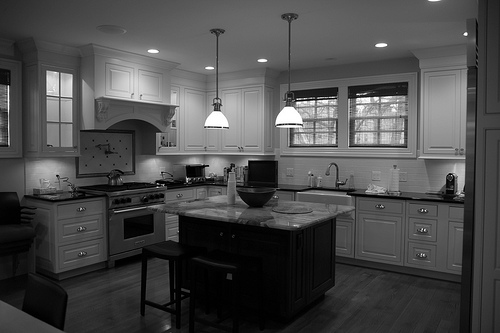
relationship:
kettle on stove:
[104, 168, 124, 188] [80, 181, 165, 196]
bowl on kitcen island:
[236, 186, 276, 208] [160, 202, 353, 319]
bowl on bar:
[236, 186, 276, 208] [146, 194, 357, 231]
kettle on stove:
[104, 168, 124, 188] [76, 181, 165, 268]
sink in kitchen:
[292, 161, 357, 197] [3, 6, 498, 322]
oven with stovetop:
[107, 195, 175, 253] [88, 173, 168, 195]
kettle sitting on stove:
[104, 168, 124, 188] [76, 181, 165, 268]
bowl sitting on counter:
[232, 181, 279, 208] [142, 182, 359, 236]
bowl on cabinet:
[236, 186, 276, 208] [159, 187, 201, 244]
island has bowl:
[149, 185, 358, 234] [231, 181, 278, 210]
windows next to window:
[346, 80, 412, 148] [285, 86, 340, 149]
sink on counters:
[305, 163, 358, 198] [300, 183, 455, 202]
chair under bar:
[135, 232, 196, 332] [158, 187, 358, 246]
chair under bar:
[211, 245, 274, 331] [158, 187, 358, 246]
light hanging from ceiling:
[204, 27, 229, 127] [1, 3, 476, 74]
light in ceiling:
[145, 42, 165, 59] [7, 2, 485, 80]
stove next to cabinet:
[76, 181, 171, 268] [24, 196, 103, 273]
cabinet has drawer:
[24, 196, 103, 273] [54, 195, 99, 220]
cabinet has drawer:
[24, 196, 103, 273] [56, 217, 108, 243]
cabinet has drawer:
[24, 196, 103, 273] [58, 237, 105, 274]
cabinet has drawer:
[25, 194, 111, 278] [55, 197, 107, 222]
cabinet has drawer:
[25, 194, 111, 278] [57, 218, 102, 242]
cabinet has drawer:
[25, 194, 111, 278] [55, 237, 103, 269]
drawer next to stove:
[55, 197, 107, 222] [76, 181, 165, 268]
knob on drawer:
[73, 191, 95, 226] [55, 199, 109, 221]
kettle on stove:
[104, 168, 124, 188] [75, 180, 162, 194]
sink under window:
[292, 161, 357, 197] [286, 87, 337, 146]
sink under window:
[292, 161, 357, 197] [347, 82, 408, 151]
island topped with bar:
[145, 194, 357, 332] [146, 194, 357, 231]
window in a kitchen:
[290, 93, 412, 146] [3, 6, 498, 322]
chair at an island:
[140, 239, 183, 329] [160, 184, 338, 307]